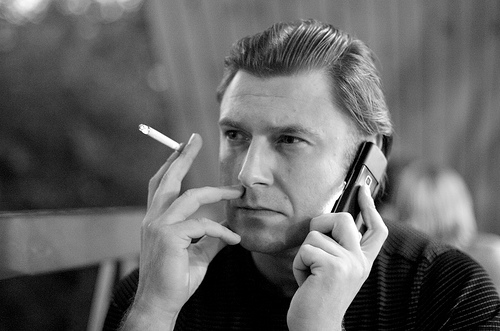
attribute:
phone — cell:
[334, 135, 404, 249]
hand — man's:
[124, 132, 268, 294]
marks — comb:
[282, 23, 349, 68]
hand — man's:
[114, 127, 258, 297]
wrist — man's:
[106, 293, 184, 329]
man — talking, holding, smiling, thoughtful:
[112, 15, 494, 328]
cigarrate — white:
[134, 122, 187, 153]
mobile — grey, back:
[330, 136, 391, 231]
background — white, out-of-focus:
[2, 3, 499, 234]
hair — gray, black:
[216, 22, 389, 137]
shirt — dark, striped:
[108, 222, 500, 331]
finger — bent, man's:
[151, 132, 389, 259]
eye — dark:
[220, 123, 301, 149]